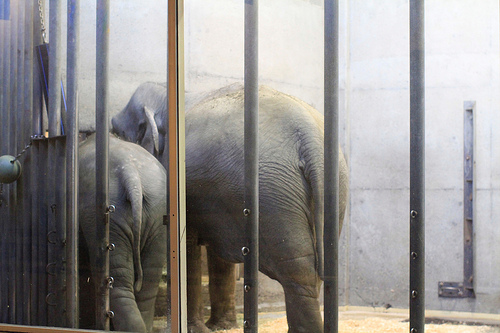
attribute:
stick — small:
[430, 83, 476, 331]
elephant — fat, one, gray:
[120, 85, 346, 331]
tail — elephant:
[117, 178, 156, 293]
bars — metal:
[242, 34, 427, 331]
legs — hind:
[110, 219, 177, 329]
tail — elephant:
[295, 153, 341, 281]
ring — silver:
[232, 197, 259, 224]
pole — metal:
[399, 26, 431, 331]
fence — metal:
[2, 25, 474, 328]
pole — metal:
[158, 11, 202, 331]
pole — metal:
[87, 11, 117, 322]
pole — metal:
[68, 20, 84, 323]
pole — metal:
[47, 10, 68, 325]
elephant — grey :
[160, 110, 354, 322]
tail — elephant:
[295, 149, 335, 274]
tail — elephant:
[125, 170, 150, 298]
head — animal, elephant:
[110, 83, 174, 151]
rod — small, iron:
[408, 1, 425, 331]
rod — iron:
[407, 1, 427, 331]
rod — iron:
[321, 0, 340, 331]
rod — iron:
[240, 0, 260, 331]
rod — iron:
[89, 2, 115, 332]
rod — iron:
[61, 0, 82, 330]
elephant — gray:
[77, 126, 169, 332]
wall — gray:
[79, 5, 499, 310]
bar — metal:
[437, 99, 480, 301]